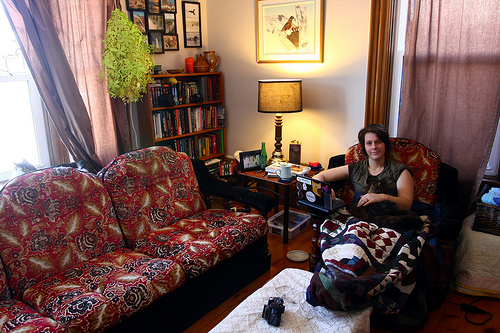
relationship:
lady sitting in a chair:
[309, 126, 416, 313] [323, 137, 460, 307]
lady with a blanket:
[309, 126, 416, 313] [306, 203, 440, 314]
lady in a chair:
[309, 126, 416, 313] [323, 137, 460, 307]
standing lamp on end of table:
[254, 78, 304, 167] [238, 161, 325, 243]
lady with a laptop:
[309, 126, 416, 313] [293, 174, 351, 216]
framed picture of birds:
[256, 2, 327, 65] [269, 4, 310, 35]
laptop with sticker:
[293, 174, 351, 216] [305, 190, 317, 203]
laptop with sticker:
[293, 174, 351, 216] [312, 181, 321, 196]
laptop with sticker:
[293, 174, 351, 216] [295, 180, 305, 203]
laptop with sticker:
[293, 174, 351, 216] [296, 175, 310, 186]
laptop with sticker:
[293, 174, 351, 216] [301, 183, 309, 192]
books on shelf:
[153, 104, 227, 140] [150, 127, 226, 143]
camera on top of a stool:
[259, 295, 287, 329] [208, 267, 374, 332]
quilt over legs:
[306, 203, 440, 314] [319, 212, 384, 308]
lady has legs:
[309, 126, 416, 313] [319, 212, 384, 308]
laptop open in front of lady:
[293, 174, 351, 216] [309, 126, 416, 313]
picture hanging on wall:
[181, 1, 202, 49] [122, 2, 208, 73]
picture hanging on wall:
[164, 33, 181, 53] [122, 2, 208, 73]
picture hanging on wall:
[162, 11, 176, 34] [122, 2, 208, 73]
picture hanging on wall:
[146, 13, 166, 33] [122, 2, 208, 73]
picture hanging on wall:
[148, 30, 164, 55] [122, 2, 208, 73]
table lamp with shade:
[254, 78, 304, 167] [257, 79, 304, 114]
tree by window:
[101, 8, 156, 150] [1, 1, 121, 169]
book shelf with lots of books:
[136, 72, 227, 178] [151, 79, 227, 162]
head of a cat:
[11, 159, 40, 173] [8, 155, 45, 174]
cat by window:
[8, 155, 45, 174] [1, 1, 121, 169]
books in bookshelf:
[153, 104, 227, 140] [136, 72, 227, 178]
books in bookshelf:
[144, 77, 220, 108] [136, 72, 227, 178]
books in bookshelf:
[168, 134, 226, 158] [136, 72, 227, 178]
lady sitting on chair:
[309, 126, 416, 313] [323, 137, 460, 307]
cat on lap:
[350, 174, 423, 234] [336, 205, 424, 236]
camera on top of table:
[259, 295, 287, 329] [208, 267, 374, 332]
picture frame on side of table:
[239, 146, 265, 174] [238, 161, 325, 243]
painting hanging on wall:
[181, 1, 202, 49] [122, 2, 208, 73]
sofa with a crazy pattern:
[0, 144, 273, 331] [13, 183, 98, 264]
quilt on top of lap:
[306, 203, 440, 314] [336, 205, 424, 236]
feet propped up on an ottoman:
[312, 266, 362, 316] [208, 267, 374, 332]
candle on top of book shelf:
[185, 57, 194, 78] [136, 72, 227, 178]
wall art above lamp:
[256, 2, 327, 65] [254, 78, 304, 167]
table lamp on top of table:
[254, 78, 304, 167] [238, 161, 325, 243]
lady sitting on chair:
[307, 123, 445, 312] [323, 137, 460, 307]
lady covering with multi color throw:
[307, 123, 445, 312] [306, 203, 440, 314]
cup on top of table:
[275, 162, 296, 181] [238, 161, 325, 243]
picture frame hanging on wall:
[256, 2, 327, 65] [222, 0, 367, 77]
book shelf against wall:
[136, 72, 227, 178] [122, 2, 208, 73]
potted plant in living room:
[101, 8, 156, 150] [1, 1, 499, 332]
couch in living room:
[0, 144, 273, 331] [1, 1, 499, 332]